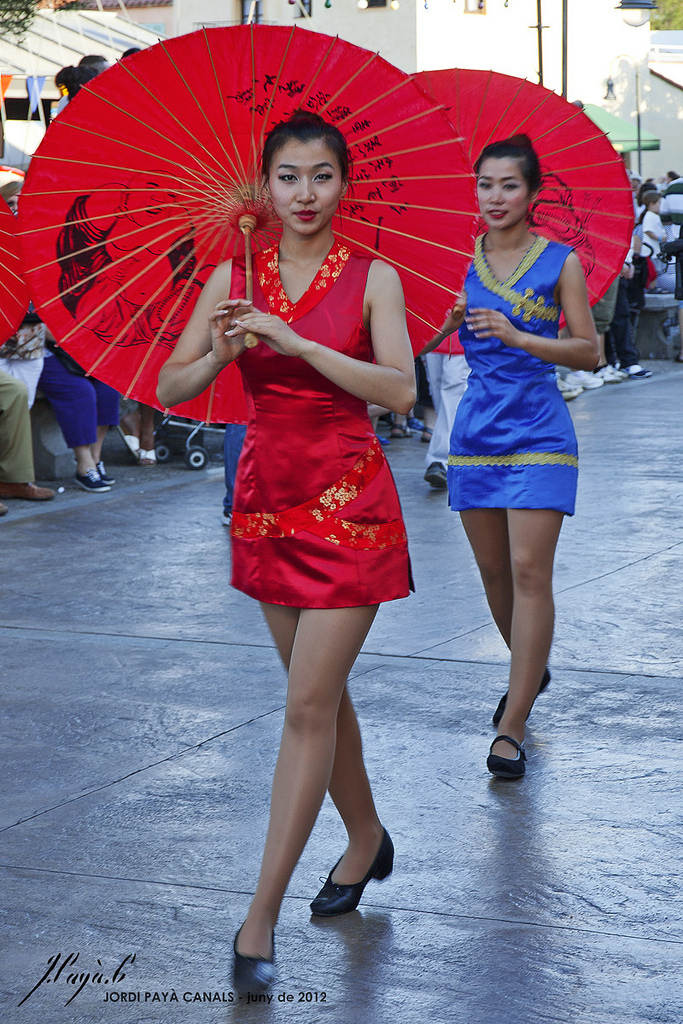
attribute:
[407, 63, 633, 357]
parisol — behind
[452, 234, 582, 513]
dress — blue, satin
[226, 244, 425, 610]
dress — red, satin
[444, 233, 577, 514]
gold dress — blue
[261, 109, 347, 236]
face — looking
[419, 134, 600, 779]
woman — asian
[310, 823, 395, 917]
shoe — black